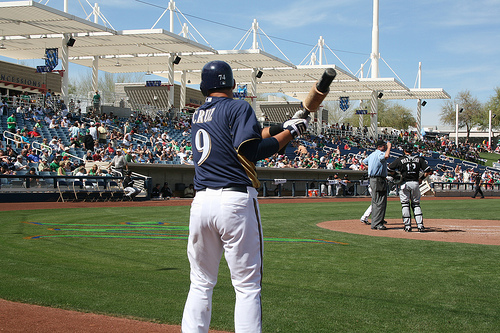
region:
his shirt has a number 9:
[176, 108, 238, 174]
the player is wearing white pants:
[181, 173, 271, 332]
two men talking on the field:
[337, 118, 443, 236]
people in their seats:
[22, 91, 178, 178]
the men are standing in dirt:
[307, 189, 457, 260]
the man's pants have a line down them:
[190, 173, 285, 325]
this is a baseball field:
[40, 204, 153, 306]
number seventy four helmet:
[210, 70, 230, 82]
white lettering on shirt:
[186, 106, 216, 121]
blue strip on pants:
[252, 216, 259, 236]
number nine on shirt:
[190, 130, 210, 165]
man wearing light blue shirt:
[370, 159, 380, 167]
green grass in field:
[312, 250, 347, 286]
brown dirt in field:
[27, 313, 51, 325]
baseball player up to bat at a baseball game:
[178, 62, 325, 332]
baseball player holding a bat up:
[176, 58, 335, 330]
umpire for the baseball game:
[359, 139, 392, 231]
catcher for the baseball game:
[398, 143, 429, 230]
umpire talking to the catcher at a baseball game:
[360, 136, 425, 236]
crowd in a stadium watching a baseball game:
[3, 94, 182, 188]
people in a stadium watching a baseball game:
[7, 89, 177, 191]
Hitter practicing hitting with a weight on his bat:
[189, 62, 335, 332]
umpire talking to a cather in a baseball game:
[362, 138, 423, 231]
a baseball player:
[153, 39, 339, 330]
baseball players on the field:
[303, 115, 474, 272]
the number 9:
[174, 117, 214, 183]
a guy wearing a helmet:
[158, 50, 310, 243]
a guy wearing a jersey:
[163, 55, 256, 241]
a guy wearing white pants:
[159, 53, 284, 330]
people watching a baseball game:
[16, 80, 166, 212]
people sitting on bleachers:
[8, 75, 148, 192]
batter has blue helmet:
[195, 30, 228, 98]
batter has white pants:
[186, 189, 283, 313]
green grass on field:
[285, 207, 351, 326]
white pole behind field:
[354, 2, 391, 79]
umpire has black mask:
[365, 135, 389, 155]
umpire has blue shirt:
[365, 155, 397, 190]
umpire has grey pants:
[357, 190, 395, 228]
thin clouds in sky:
[412, 2, 476, 84]